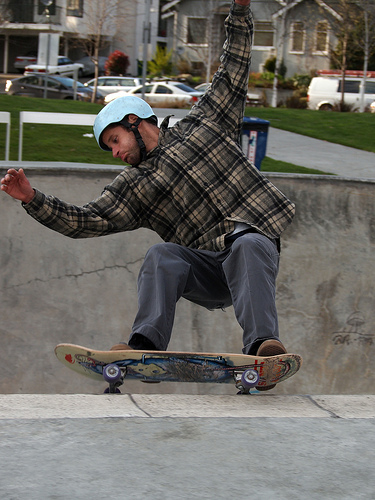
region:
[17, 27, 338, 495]
Picture taken outside.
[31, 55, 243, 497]
Picture taken during the day.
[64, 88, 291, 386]
A man on a skateboard.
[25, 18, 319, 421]
The man is doing a trick.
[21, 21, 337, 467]
The man is in a skateboard park.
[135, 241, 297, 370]
The man is wearing gray pants.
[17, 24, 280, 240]
The man's arms are in the air.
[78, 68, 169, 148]
The man is wearing a helmet.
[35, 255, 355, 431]
The skateboard is on the edge.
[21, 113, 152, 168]
Grassy area behind park.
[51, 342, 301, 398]
A skateboard.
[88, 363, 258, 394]
Purple wheels on the bottom of a skateboard.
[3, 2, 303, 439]
A man doing a trick on a skateboard.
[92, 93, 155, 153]
A light colored skateboarding helmet.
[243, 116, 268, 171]
A blue trash can.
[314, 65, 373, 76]
An orange ladder.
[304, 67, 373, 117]
A white work van.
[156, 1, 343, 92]
A blue house with white trim.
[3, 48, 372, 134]
Vehicles that are parked.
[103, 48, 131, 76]
A red bush.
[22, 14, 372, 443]
skateboarder wearing a blue helmet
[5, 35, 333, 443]
male skateboarding on ramp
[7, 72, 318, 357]
skateboarder wearing a plaid shirt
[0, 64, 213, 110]
parked cars on street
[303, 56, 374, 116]
white van parked on street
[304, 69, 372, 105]
white van with a red ladder on top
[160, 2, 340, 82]
blue house in background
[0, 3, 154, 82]
white two story house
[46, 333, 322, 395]
skateboard with four wheels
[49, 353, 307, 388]
bottom of skateboard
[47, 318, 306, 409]
this is a skate board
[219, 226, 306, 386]
the leg of a man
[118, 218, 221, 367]
the leg of a aman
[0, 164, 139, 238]
the hand of a man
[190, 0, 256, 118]
the hand of a man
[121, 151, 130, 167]
the mouth of a man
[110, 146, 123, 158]
the nose of a man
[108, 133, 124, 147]
the eye of a man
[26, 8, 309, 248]
this is a checked shirt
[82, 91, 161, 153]
this is a helmet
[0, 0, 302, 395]
Man skateboarding on halfpipe.